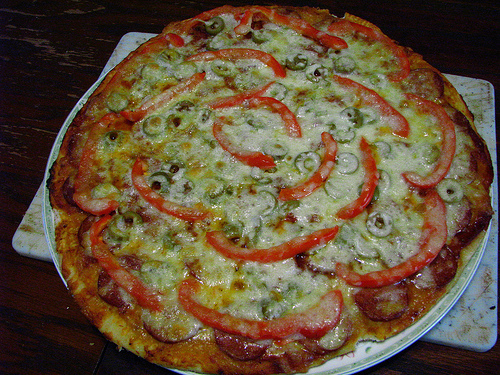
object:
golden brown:
[48, 8, 493, 375]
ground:
[401, 119, 442, 169]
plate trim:
[358, 344, 397, 366]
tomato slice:
[335, 137, 377, 219]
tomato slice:
[206, 226, 339, 265]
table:
[0, 0, 500, 375]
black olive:
[151, 181, 161, 191]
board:
[9, 32, 500, 351]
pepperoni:
[62, 122, 478, 360]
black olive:
[314, 69, 321, 76]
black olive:
[54, 19, 441, 258]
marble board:
[10, 32, 500, 351]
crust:
[84, 313, 232, 373]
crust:
[48, 111, 92, 294]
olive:
[90, 16, 460, 318]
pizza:
[49, 6, 494, 375]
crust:
[368, 298, 431, 338]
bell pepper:
[72, 8, 454, 338]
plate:
[46, 71, 493, 375]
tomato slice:
[132, 157, 204, 221]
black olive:
[376, 218, 384, 224]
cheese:
[92, 16, 474, 346]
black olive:
[211, 25, 215, 29]